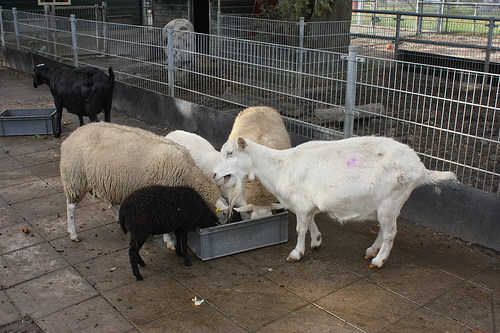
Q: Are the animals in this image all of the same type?
A: No, they are goats and cows.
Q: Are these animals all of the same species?
A: No, there are both goats and cows.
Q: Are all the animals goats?
A: No, there are both goats and cows.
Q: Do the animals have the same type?
A: No, there are both goats and cows.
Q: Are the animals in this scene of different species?
A: Yes, they are goats and cows.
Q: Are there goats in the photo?
A: Yes, there is a goat.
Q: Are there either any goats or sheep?
A: Yes, there is a goat.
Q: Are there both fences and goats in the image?
A: Yes, there are both a goat and a fence.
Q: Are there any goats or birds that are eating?
A: Yes, the goat is eating.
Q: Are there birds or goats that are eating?
A: Yes, the goat is eating.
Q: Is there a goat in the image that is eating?
A: Yes, there is a goat that is eating.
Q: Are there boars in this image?
A: No, there are no boars.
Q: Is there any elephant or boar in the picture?
A: No, there are no boars or elephants.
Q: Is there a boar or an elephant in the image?
A: No, there are no boars or elephants.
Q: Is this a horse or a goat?
A: This is a goat.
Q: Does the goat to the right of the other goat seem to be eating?
A: Yes, the goat is eating.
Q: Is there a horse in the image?
A: No, there are no horses.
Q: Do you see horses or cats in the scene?
A: No, there are no horses or cats.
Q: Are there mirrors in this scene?
A: No, there are no mirrors.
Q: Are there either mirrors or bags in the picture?
A: No, there are no mirrors or bags.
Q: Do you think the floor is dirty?
A: Yes, the floor is dirty.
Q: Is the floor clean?
A: No, the floor is dirty.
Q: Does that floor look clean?
A: No, the floor is dirty.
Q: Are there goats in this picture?
A: Yes, there is a goat.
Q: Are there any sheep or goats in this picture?
A: Yes, there is a goat.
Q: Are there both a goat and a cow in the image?
A: Yes, there are both a goat and a cow.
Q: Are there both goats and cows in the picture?
A: Yes, there are both a goat and cows.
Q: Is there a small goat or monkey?
A: Yes, there is a small goat.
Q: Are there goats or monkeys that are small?
A: Yes, the goat is small.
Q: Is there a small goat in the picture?
A: Yes, there is a small goat.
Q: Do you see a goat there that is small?
A: Yes, there is a goat that is small.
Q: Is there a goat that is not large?
A: Yes, there is a small goat.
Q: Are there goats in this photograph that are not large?
A: Yes, there is a small goat.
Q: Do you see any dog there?
A: No, there are no dogs.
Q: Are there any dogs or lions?
A: No, there are no dogs or lions.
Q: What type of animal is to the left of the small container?
A: The animal is a goat.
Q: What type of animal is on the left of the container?
A: The animal is a goat.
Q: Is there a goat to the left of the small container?
A: Yes, there is a goat to the left of the container.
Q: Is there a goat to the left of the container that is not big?
A: Yes, there is a goat to the left of the container.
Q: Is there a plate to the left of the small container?
A: No, there is a goat to the left of the container.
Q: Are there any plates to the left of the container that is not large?
A: No, there is a goat to the left of the container.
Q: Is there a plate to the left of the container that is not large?
A: No, there is a goat to the left of the container.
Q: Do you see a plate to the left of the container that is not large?
A: No, there is a goat to the left of the container.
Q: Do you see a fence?
A: Yes, there is a fence.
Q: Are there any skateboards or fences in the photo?
A: Yes, there is a fence.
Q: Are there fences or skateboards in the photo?
A: Yes, there is a fence.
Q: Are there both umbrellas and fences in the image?
A: No, there is a fence but no umbrellas.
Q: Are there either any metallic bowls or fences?
A: Yes, there is a metal fence.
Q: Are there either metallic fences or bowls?
A: Yes, there is a metal fence.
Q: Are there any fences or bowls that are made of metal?
A: Yes, the fence is made of metal.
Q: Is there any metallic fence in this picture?
A: Yes, there is a metal fence.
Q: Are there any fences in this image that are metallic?
A: Yes, there is a fence that is metallic.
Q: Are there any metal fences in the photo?
A: Yes, there is a fence that is made of metal.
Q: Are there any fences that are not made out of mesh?
A: Yes, there is a fence that is made of metal.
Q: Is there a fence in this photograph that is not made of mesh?
A: Yes, there is a fence that is made of metal.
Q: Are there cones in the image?
A: No, there are no cones.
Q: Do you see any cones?
A: No, there are no cones.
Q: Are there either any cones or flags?
A: No, there are no cones or flags.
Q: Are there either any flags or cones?
A: No, there are no cones or flags.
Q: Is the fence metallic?
A: Yes, the fence is metallic.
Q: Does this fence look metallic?
A: Yes, the fence is metallic.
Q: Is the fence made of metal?
A: Yes, the fence is made of metal.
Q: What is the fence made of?
A: The fence is made of metal.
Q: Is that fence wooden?
A: No, the fence is metallic.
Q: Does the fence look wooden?
A: No, the fence is metallic.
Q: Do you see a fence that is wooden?
A: No, there is a fence but it is metallic.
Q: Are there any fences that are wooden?
A: No, there is a fence but it is metallic.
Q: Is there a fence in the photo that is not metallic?
A: No, there is a fence but it is metallic.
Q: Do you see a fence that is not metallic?
A: No, there is a fence but it is metallic.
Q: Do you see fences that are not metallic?
A: No, there is a fence but it is metallic.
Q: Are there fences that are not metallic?
A: No, there is a fence but it is metallic.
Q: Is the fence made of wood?
A: No, the fence is made of metal.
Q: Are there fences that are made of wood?
A: No, there is a fence but it is made of metal.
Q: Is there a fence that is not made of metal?
A: No, there is a fence but it is made of metal.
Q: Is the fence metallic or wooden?
A: The fence is metallic.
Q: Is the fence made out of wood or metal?
A: The fence is made of metal.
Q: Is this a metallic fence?
A: Yes, this is a metallic fence.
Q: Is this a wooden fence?
A: No, this is a metallic fence.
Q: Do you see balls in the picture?
A: No, there are no balls.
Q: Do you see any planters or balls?
A: No, there are no balls or planters.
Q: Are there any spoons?
A: No, there are no spoons.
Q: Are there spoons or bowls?
A: No, there are no spoons or bowls.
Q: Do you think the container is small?
A: Yes, the container is small.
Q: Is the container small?
A: Yes, the container is small.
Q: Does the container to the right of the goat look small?
A: Yes, the container is small.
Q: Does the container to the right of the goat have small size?
A: Yes, the container is small.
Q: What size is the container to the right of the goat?
A: The container is small.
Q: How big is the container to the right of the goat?
A: The container is small.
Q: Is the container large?
A: No, the container is small.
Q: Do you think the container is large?
A: No, the container is small.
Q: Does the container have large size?
A: No, the container is small.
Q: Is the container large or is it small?
A: The container is small.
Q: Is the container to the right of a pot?
A: No, the container is to the right of the goat.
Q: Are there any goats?
A: Yes, there is a goat.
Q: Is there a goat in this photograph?
A: Yes, there is a goat.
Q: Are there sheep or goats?
A: Yes, there is a goat.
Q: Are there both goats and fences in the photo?
A: Yes, there are both a goat and a fence.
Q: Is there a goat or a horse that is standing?
A: Yes, the goat is standing.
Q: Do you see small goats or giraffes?
A: Yes, there is a small goat.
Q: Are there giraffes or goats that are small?
A: Yes, the goat is small.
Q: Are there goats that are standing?
A: Yes, there is a goat that is standing.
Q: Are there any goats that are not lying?
A: Yes, there is a goat that is standing.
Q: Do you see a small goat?
A: Yes, there is a small goat.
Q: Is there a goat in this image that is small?
A: Yes, there is a goat that is small.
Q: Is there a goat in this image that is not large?
A: Yes, there is a small goat.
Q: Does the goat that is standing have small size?
A: Yes, the goat is small.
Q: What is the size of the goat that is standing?
A: The goat is small.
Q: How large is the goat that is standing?
A: The goat is small.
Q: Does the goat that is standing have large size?
A: No, the goat is small.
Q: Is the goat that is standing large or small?
A: The goat is small.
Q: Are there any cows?
A: Yes, there is a cow.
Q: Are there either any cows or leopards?
A: Yes, there is a cow.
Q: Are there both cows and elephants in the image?
A: No, there is a cow but no elephants.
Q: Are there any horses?
A: No, there are no horses.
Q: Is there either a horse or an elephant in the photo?
A: No, there are no horses or elephants.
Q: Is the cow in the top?
A: Yes, the cow is in the top of the image.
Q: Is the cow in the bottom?
A: No, the cow is in the top of the image.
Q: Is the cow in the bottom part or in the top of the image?
A: The cow is in the top of the image.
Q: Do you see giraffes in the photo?
A: No, there are no giraffes.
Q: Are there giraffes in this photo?
A: No, there are no giraffes.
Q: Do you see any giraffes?
A: No, there are no giraffes.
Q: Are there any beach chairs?
A: No, there are no beach chairs.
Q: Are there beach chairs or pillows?
A: No, there are no beach chairs or pillows.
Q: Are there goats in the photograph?
A: Yes, there is a goat.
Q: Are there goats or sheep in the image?
A: Yes, there is a goat.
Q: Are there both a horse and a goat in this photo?
A: No, there is a goat but no horses.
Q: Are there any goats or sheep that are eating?
A: Yes, the goat is eating.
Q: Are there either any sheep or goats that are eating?
A: Yes, the goat is eating.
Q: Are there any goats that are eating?
A: Yes, there is a goat that is eating.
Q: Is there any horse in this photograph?
A: No, there are no horses.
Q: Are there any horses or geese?
A: No, there are no horses or geese.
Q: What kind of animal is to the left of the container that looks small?
A: The animal is a goat.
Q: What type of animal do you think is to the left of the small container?
A: The animal is a goat.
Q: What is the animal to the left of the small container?
A: The animal is a goat.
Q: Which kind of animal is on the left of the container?
A: The animal is a goat.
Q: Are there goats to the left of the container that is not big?
A: Yes, there is a goat to the left of the container.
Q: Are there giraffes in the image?
A: No, there are no giraffes.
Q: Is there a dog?
A: No, there are no dogs.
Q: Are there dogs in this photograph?
A: No, there are no dogs.